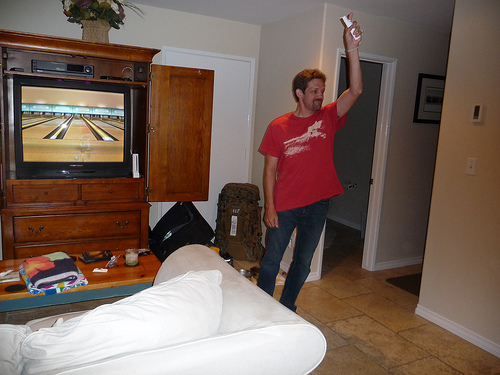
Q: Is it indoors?
A: Yes, it is indoors.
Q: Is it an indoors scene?
A: Yes, it is indoors.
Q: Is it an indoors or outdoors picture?
A: It is indoors.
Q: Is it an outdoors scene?
A: No, it is indoors.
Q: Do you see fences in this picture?
A: Yes, there is a fence.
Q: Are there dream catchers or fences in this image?
A: Yes, there is a fence.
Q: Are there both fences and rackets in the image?
A: No, there is a fence but no rackets.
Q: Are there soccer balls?
A: No, there are no soccer balls.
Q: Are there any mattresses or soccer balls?
A: No, there are no soccer balls or mattresses.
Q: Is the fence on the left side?
A: Yes, the fence is on the left of the image.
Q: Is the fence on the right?
A: No, the fence is on the left of the image.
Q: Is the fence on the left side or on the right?
A: The fence is on the left of the image.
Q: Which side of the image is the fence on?
A: The fence is on the left of the image.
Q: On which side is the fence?
A: The fence is on the left of the image.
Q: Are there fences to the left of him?
A: Yes, there is a fence to the left of the man.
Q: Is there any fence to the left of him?
A: Yes, there is a fence to the left of the man.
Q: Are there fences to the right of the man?
A: No, the fence is to the left of the man.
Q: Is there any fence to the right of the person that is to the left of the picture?
A: No, the fence is to the left of the man.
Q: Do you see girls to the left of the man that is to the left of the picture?
A: No, there is a fence to the left of the man.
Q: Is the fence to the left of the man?
A: Yes, the fence is to the left of the man.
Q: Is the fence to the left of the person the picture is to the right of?
A: Yes, the fence is to the left of the man.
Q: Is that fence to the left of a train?
A: No, the fence is to the left of the man.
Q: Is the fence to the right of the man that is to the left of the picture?
A: No, the fence is to the left of the man.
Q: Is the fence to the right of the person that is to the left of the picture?
A: No, the fence is to the left of the man.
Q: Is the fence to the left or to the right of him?
A: The fence is to the left of the man.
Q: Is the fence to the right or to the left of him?
A: The fence is to the left of the man.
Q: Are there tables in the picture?
A: Yes, there is a table.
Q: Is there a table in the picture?
A: Yes, there is a table.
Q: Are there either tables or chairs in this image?
A: Yes, there is a table.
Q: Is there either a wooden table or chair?
A: Yes, there is a wood table.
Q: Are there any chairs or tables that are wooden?
A: Yes, the table is wooden.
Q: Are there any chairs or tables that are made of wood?
A: Yes, the table is made of wood.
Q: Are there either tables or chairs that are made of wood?
A: Yes, the table is made of wood.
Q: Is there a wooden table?
A: Yes, there is a wood table.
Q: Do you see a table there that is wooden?
A: Yes, there is a table that is wooden.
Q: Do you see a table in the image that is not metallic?
A: Yes, there is a wooden table.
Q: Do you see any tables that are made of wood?
A: Yes, there is a table that is made of wood.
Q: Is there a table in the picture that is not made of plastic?
A: Yes, there is a table that is made of wood.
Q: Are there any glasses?
A: No, there are no glasses.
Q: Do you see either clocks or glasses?
A: No, there are no glasses or clocks.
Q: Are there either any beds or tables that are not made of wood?
A: No, there is a table but it is made of wood.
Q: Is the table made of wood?
A: Yes, the table is made of wood.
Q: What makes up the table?
A: The table is made of wood.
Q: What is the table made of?
A: The table is made of wood.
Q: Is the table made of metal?
A: No, the table is made of wood.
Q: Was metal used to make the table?
A: No, the table is made of wood.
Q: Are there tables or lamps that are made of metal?
A: No, there is a table but it is made of wood.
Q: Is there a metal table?
A: No, there is a table but it is made of wood.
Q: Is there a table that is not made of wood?
A: No, there is a table but it is made of wood.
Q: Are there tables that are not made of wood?
A: No, there is a table but it is made of wood.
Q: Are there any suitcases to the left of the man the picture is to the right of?
A: Yes, there is a suitcase to the left of the man.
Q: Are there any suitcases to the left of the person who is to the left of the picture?
A: Yes, there is a suitcase to the left of the man.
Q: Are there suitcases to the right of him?
A: No, the suitcase is to the left of the man.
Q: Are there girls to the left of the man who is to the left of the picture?
A: No, there is a suitcase to the left of the man.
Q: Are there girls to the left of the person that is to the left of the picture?
A: No, there is a suitcase to the left of the man.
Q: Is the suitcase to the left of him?
A: Yes, the suitcase is to the left of the man.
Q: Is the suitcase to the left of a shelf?
A: No, the suitcase is to the left of the man.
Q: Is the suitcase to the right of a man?
A: No, the suitcase is to the left of a man.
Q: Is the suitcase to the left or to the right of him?
A: The suitcase is to the left of the man.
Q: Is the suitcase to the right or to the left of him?
A: The suitcase is to the left of the man.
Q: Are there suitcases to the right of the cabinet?
A: Yes, there is a suitcase to the right of the cabinet.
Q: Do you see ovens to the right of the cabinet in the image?
A: No, there is a suitcase to the right of the cabinet.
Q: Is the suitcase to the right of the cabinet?
A: Yes, the suitcase is to the right of the cabinet.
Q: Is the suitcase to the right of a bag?
A: No, the suitcase is to the right of the cabinet.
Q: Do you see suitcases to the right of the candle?
A: Yes, there is a suitcase to the right of the candle.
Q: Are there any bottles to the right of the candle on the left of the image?
A: No, there is a suitcase to the right of the candle.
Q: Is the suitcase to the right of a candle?
A: Yes, the suitcase is to the right of a candle.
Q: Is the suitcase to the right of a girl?
A: No, the suitcase is to the right of a candle.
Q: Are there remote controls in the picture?
A: Yes, there is a remote control.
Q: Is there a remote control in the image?
A: Yes, there is a remote control.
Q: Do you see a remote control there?
A: Yes, there is a remote control.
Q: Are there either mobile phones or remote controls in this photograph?
A: Yes, there is a remote control.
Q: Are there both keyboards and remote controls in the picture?
A: No, there is a remote control but no keyboards.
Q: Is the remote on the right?
A: Yes, the remote is on the right of the image.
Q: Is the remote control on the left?
A: No, the remote control is on the right of the image.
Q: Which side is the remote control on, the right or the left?
A: The remote control is on the right of the image.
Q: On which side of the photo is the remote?
A: The remote is on the right of the image.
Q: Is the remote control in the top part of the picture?
A: Yes, the remote control is in the top of the image.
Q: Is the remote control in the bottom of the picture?
A: No, the remote control is in the top of the image.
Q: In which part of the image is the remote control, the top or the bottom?
A: The remote control is in the top of the image.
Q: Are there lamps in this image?
A: No, there are no lamps.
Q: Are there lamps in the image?
A: No, there are no lamps.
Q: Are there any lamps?
A: No, there are no lamps.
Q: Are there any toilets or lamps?
A: No, there are no lamps or toilets.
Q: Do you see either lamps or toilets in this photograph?
A: No, there are no lamps or toilets.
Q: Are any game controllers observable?
A: Yes, there is a game controller.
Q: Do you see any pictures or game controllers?
A: Yes, there is a game controller.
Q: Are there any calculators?
A: No, there are no calculators.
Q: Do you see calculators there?
A: No, there are no calculators.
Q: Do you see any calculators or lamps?
A: No, there are no calculators or lamps.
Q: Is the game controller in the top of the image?
A: Yes, the game controller is in the top of the image.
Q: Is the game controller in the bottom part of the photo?
A: No, the game controller is in the top of the image.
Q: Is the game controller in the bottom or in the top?
A: The game controller is in the top of the image.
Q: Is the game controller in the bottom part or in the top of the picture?
A: The game controller is in the top of the image.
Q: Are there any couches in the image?
A: Yes, there is a couch.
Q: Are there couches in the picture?
A: Yes, there is a couch.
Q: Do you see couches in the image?
A: Yes, there is a couch.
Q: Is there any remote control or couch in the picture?
A: Yes, there is a couch.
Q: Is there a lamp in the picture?
A: No, there are no lamps.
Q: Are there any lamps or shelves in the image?
A: No, there are no lamps or shelves.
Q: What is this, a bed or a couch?
A: This is a couch.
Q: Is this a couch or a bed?
A: This is a couch.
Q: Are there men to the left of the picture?
A: Yes, there is a man to the left of the picture.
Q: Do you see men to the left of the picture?
A: Yes, there is a man to the left of the picture.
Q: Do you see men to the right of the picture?
A: No, the man is to the left of the picture.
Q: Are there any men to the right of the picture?
A: No, the man is to the left of the picture.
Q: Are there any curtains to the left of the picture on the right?
A: No, there is a man to the left of the picture.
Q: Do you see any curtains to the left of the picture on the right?
A: No, there is a man to the left of the picture.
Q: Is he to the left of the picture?
A: Yes, the man is to the left of the picture.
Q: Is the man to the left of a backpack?
A: No, the man is to the left of the picture.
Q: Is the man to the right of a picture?
A: No, the man is to the left of a picture.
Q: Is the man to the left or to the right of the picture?
A: The man is to the left of the picture.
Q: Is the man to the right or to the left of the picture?
A: The man is to the left of the picture.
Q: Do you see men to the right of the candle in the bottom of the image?
A: Yes, there is a man to the right of the candle.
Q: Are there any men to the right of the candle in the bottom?
A: Yes, there is a man to the right of the candle.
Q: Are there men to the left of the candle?
A: No, the man is to the right of the candle.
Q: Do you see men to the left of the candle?
A: No, the man is to the right of the candle.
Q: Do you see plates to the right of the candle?
A: No, there is a man to the right of the candle.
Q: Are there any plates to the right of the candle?
A: No, there is a man to the right of the candle.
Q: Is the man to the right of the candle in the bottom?
A: Yes, the man is to the right of the candle.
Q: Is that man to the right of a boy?
A: No, the man is to the right of the candle.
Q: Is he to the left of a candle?
A: No, the man is to the right of a candle.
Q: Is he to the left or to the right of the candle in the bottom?
A: The man is to the right of the candle.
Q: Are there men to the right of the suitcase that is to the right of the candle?
A: Yes, there is a man to the right of the suitcase.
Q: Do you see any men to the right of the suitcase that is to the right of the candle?
A: Yes, there is a man to the right of the suitcase.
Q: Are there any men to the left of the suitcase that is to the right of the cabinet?
A: No, the man is to the right of the suitcase.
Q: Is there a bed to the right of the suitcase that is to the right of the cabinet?
A: No, there is a man to the right of the suitcase.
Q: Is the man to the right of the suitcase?
A: Yes, the man is to the right of the suitcase.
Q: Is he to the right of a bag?
A: No, the man is to the right of the suitcase.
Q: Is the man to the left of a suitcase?
A: No, the man is to the right of a suitcase.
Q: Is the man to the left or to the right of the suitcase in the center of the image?
A: The man is to the right of the suitcase.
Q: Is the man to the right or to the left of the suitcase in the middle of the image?
A: The man is to the right of the suitcase.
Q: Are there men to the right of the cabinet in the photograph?
A: Yes, there is a man to the right of the cabinet.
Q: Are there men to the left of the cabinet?
A: No, the man is to the right of the cabinet.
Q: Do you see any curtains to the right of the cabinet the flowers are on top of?
A: No, there is a man to the right of the cabinet.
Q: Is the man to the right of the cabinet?
A: Yes, the man is to the right of the cabinet.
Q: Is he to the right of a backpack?
A: No, the man is to the right of the cabinet.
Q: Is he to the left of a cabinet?
A: No, the man is to the right of a cabinet.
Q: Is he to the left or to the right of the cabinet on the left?
A: The man is to the right of the cabinet.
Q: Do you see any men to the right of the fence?
A: Yes, there is a man to the right of the fence.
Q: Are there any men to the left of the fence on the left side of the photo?
A: No, the man is to the right of the fence.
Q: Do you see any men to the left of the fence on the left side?
A: No, the man is to the right of the fence.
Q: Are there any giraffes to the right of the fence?
A: No, there is a man to the right of the fence.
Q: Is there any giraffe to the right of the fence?
A: No, there is a man to the right of the fence.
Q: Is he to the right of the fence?
A: Yes, the man is to the right of the fence.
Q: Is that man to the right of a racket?
A: No, the man is to the right of the fence.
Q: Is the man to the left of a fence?
A: No, the man is to the right of a fence.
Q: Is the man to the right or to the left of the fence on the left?
A: The man is to the right of the fence.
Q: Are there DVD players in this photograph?
A: Yes, there is a DVD player.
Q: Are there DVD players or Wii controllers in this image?
A: Yes, there is a DVD player.